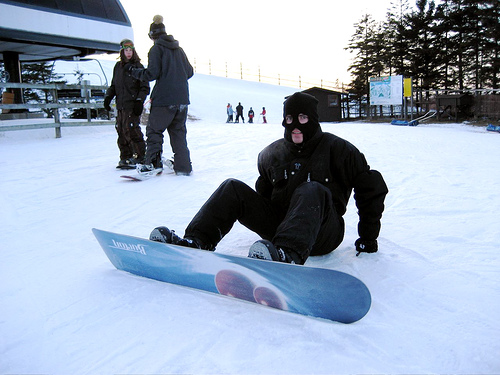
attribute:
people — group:
[222, 101, 270, 122]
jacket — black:
[253, 132, 393, 243]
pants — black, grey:
[185, 175, 346, 261]